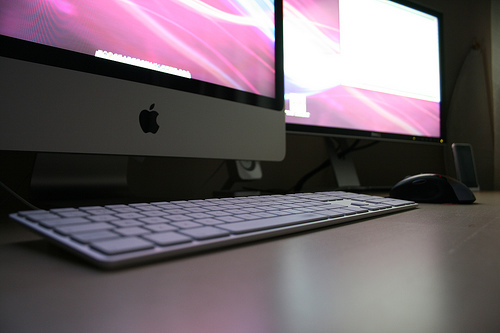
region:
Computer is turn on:
[0, 0, 310, 262]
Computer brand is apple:
[5, 0, 295, 275]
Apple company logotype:
[132, 96, 165, 138]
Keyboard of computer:
[7, 173, 413, 267]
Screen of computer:
[274, 0, 446, 156]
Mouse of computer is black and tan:
[376, 168, 481, 208]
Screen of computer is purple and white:
[19, 0, 280, 105]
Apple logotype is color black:
[130, 96, 166, 138]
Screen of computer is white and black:
[287, 0, 442, 142]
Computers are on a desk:
[6, 3, 498, 331]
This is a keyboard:
[28, 156, 420, 271]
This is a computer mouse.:
[362, 151, 476, 228]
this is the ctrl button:
[94, 237, 146, 257]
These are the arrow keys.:
[355, 198, 394, 215]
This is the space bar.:
[206, 213, 350, 237]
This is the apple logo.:
[120, 91, 191, 146]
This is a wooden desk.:
[263, 250, 391, 305]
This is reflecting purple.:
[314, 235, 405, 299]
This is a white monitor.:
[178, 105, 234, 147]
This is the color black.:
[403, 172, 430, 192]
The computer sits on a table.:
[2, 0, 477, 290]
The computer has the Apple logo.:
[132, 97, 178, 147]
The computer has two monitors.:
[0, 0, 470, 176]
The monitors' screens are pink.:
[0, 0, 456, 148]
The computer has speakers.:
[439, 133, 490, 195]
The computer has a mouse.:
[374, 163, 485, 211]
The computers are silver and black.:
[2, 0, 462, 284]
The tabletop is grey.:
[2, 188, 497, 330]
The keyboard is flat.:
[2, 157, 442, 283]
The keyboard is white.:
[1, 164, 433, 289]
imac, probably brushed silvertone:
[0, 1, 285, 199]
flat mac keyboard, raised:
[7, 179, 421, 274]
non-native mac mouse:
[377, 165, 483, 210]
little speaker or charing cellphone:
[445, 135, 481, 190]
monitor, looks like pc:
[281, 0, 451, 145]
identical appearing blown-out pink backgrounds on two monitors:
[1, 0, 444, 144]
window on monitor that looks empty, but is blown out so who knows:
[331, 0, 438, 105]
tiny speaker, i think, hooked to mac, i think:
[227, 158, 274, 194]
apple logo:
[134, 98, 166, 141]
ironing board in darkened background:
[441, 33, 496, 183]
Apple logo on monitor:
[114, 90, 193, 150]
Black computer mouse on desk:
[385, 168, 473, 199]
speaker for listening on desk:
[444, 138, 486, 183]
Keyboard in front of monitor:
[8, 184, 441, 262]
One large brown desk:
[337, 268, 494, 327]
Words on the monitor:
[93, 42, 214, 84]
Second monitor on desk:
[282, 0, 451, 136]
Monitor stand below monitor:
[325, 148, 361, 183]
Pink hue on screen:
[129, 5, 267, 59]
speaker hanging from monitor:
[232, 161, 269, 182]